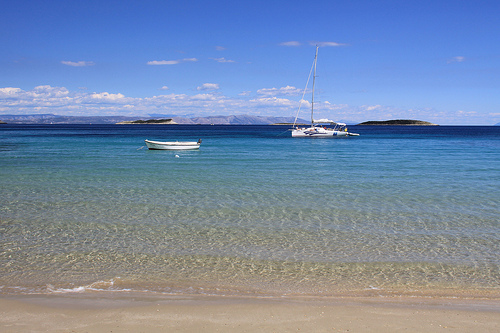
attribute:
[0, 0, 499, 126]
sky — blue, clear, beautiful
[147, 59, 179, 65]
cloud — white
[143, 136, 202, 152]
boat — white, small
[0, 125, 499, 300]
water — pristine, calm, beautiful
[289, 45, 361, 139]
boat — large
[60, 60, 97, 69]
cloud — white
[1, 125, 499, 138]
water — dark blue